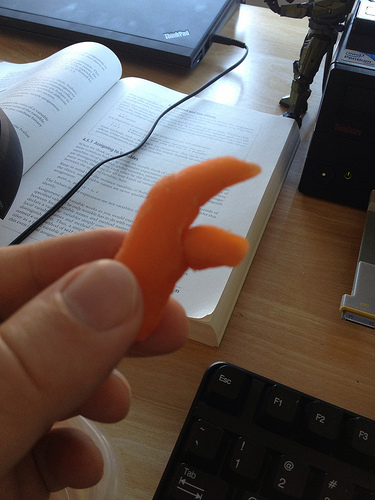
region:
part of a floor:
[136, 453, 155, 482]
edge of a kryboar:
[171, 429, 183, 447]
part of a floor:
[124, 409, 147, 445]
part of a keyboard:
[207, 414, 244, 457]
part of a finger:
[93, 362, 125, 423]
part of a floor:
[133, 430, 167, 478]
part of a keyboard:
[241, 376, 279, 421]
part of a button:
[222, 417, 259, 474]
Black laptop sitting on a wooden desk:
[1, 0, 243, 81]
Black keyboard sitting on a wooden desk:
[162, 357, 373, 498]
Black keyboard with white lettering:
[166, 358, 320, 498]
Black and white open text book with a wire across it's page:
[31, 54, 261, 183]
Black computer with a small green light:
[306, 52, 374, 222]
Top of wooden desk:
[250, 249, 345, 384]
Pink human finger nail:
[48, 264, 154, 339]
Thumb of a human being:
[8, 260, 143, 389]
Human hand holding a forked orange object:
[11, 153, 277, 355]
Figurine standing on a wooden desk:
[280, 0, 361, 122]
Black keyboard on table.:
[148, 361, 373, 497]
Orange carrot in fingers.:
[113, 145, 245, 350]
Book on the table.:
[5, 51, 262, 338]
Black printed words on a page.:
[104, 77, 256, 214]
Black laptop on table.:
[8, 0, 282, 76]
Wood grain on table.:
[237, 311, 340, 368]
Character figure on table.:
[261, 0, 337, 116]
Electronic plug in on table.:
[338, 207, 374, 333]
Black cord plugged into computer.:
[196, 23, 253, 101]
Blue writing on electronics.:
[339, 44, 373, 78]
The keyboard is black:
[130, 360, 369, 497]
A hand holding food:
[4, 153, 276, 483]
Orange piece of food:
[97, 141, 286, 336]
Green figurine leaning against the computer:
[254, 3, 356, 131]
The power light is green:
[332, 164, 357, 185]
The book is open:
[3, 40, 300, 340]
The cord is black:
[2, 19, 261, 233]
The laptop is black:
[10, 1, 243, 70]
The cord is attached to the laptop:
[8, 26, 264, 256]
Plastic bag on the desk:
[46, 412, 145, 497]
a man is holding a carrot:
[67, 153, 263, 348]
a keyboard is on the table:
[148, 357, 374, 495]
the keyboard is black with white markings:
[140, 363, 374, 496]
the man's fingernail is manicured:
[54, 256, 140, 341]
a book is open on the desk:
[4, 42, 301, 345]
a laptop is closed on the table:
[1, 0, 236, 71]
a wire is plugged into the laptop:
[207, 32, 252, 78]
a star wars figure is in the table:
[259, 0, 358, 122]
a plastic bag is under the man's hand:
[37, 404, 132, 498]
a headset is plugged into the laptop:
[1, 31, 250, 251]